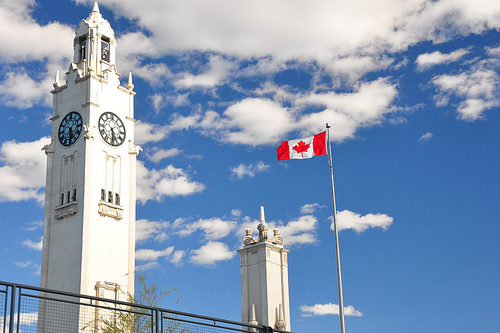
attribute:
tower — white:
[33, 3, 142, 332]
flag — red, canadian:
[275, 128, 329, 161]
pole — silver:
[325, 122, 353, 332]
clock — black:
[97, 111, 132, 149]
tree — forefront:
[82, 273, 188, 332]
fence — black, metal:
[1, 276, 299, 332]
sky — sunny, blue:
[0, 0, 499, 332]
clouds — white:
[170, 78, 400, 151]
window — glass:
[99, 36, 113, 65]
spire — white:
[71, 2, 118, 77]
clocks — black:
[57, 110, 130, 150]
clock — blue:
[58, 111, 85, 146]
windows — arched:
[99, 153, 126, 220]